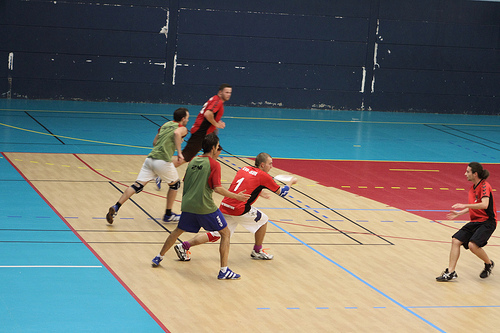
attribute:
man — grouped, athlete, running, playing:
[173, 82, 234, 169]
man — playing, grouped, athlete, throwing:
[218, 153, 299, 262]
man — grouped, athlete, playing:
[105, 109, 190, 224]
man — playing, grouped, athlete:
[152, 133, 252, 281]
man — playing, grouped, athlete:
[434, 163, 497, 284]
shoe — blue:
[218, 267, 242, 281]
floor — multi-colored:
[2, 99, 497, 331]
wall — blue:
[0, 1, 498, 114]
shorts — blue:
[177, 211, 227, 238]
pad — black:
[169, 179, 182, 190]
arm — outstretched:
[214, 186, 254, 202]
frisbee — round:
[273, 172, 297, 185]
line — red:
[0, 152, 171, 331]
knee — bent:
[468, 241, 481, 250]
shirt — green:
[148, 118, 190, 161]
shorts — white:
[210, 203, 270, 235]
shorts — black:
[452, 216, 498, 251]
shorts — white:
[137, 159, 182, 185]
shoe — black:
[480, 260, 494, 278]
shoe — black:
[435, 268, 460, 282]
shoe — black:
[165, 211, 182, 222]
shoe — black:
[105, 204, 120, 224]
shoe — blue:
[152, 255, 165, 267]